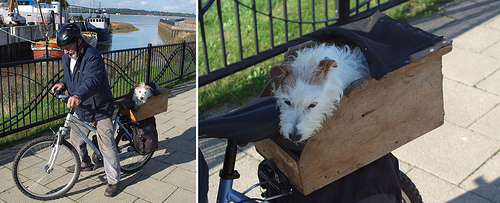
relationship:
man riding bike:
[53, 23, 123, 197] [11, 81, 169, 201]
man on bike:
[53, 23, 123, 197] [11, 81, 169, 201]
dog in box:
[130, 82, 155, 112] [116, 86, 169, 122]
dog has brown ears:
[130, 82, 155, 112] [132, 83, 154, 90]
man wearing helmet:
[53, 23, 123, 197] [56, 21, 83, 50]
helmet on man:
[56, 21, 83, 50] [53, 23, 123, 197]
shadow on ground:
[118, 126, 197, 192] [2, 43, 197, 201]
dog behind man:
[130, 82, 155, 112] [53, 23, 123, 197]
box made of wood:
[116, 86, 169, 122] [117, 85, 168, 122]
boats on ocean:
[32, 18, 111, 60] [66, 11, 198, 54]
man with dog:
[53, 23, 123, 197] [130, 82, 155, 112]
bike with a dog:
[11, 81, 169, 201] [130, 82, 155, 112]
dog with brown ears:
[130, 82, 155, 112] [132, 83, 154, 90]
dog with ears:
[130, 82, 155, 112] [132, 83, 154, 90]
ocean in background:
[66, 11, 198, 54] [1, 2, 196, 64]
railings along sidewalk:
[1, 42, 196, 136] [11, 81, 169, 201]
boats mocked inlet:
[32, 18, 111, 60] [68, 16, 137, 34]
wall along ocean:
[1, 29, 56, 66] [66, 11, 198, 54]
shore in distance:
[67, 5, 195, 19] [60, 2, 197, 16]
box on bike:
[116, 86, 169, 122] [11, 81, 169, 201]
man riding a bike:
[53, 23, 123, 197] [11, 81, 169, 201]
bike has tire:
[11, 81, 169, 201] [116, 121, 159, 175]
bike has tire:
[11, 81, 169, 201] [11, 134, 82, 201]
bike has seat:
[11, 81, 169, 201] [113, 99, 136, 110]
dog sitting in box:
[130, 82, 155, 112] [116, 86, 169, 122]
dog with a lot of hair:
[130, 82, 155, 112] [137, 83, 147, 90]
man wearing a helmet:
[53, 23, 123, 197] [56, 21, 83, 50]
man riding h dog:
[53, 23, 123, 197] [130, 82, 155, 112]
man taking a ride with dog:
[53, 23, 123, 197] [130, 82, 155, 112]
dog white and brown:
[130, 82, 155, 112] [270, 65, 293, 88]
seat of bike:
[113, 99, 136, 110] [11, 81, 169, 201]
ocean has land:
[66, 11, 198, 54] [108, 20, 139, 34]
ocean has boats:
[66, 11, 198, 54] [32, 18, 111, 60]